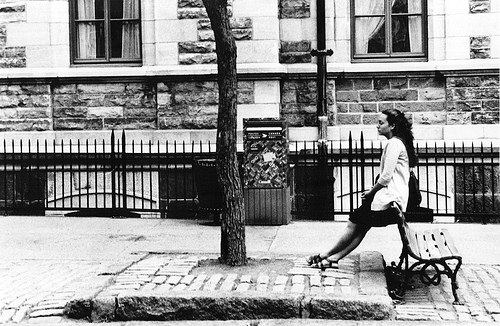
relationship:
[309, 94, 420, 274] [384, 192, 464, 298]
lady sitting on bench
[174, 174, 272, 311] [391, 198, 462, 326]
tree beside bench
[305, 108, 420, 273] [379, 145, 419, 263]
lady wearing white shirt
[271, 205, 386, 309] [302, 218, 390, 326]
these are legs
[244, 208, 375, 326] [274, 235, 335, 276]
these are ladies shoes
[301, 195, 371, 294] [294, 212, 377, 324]
these are legs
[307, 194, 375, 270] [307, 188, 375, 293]
crossed legs are crossed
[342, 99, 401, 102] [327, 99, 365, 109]
window on house right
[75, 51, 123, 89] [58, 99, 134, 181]
window on house left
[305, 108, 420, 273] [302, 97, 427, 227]
lady with white shirt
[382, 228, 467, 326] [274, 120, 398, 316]
empty bench behind woman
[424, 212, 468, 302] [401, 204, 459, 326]
brown wood on bench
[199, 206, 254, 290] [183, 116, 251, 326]
bottom of tall tree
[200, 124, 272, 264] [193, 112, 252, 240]
center of tall tree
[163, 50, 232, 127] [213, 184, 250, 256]
top of tall tree